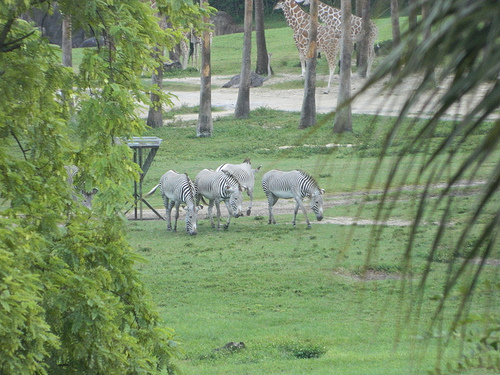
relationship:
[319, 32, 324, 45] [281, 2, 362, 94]
spot on giraffe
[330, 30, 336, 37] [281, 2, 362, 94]
spot on giraffe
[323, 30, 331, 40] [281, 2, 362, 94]
spot on giraffe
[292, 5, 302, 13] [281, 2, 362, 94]
spot on giraffe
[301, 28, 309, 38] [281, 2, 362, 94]
spot on giraffe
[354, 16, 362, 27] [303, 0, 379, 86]
spot on giraffe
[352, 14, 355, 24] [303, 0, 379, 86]
spot on giraffe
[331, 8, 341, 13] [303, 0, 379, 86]
spot on giraffe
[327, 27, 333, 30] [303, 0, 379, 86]
spot on giraffe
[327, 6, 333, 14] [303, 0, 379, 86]
spot on giraffe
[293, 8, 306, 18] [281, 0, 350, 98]
spot on giraffe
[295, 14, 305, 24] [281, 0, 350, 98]
spot on giraffe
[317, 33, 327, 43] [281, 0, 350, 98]
spot on giraffe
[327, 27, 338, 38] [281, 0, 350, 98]
spot on giraffe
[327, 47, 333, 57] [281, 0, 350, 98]
spot on giraffe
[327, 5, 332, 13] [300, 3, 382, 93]
spot on giraffe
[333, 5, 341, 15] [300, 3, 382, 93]
spot on giraffe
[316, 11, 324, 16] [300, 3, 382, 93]
spot on giraffe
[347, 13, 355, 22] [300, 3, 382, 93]
spot on giraffe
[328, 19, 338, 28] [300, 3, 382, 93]
spot on giraffe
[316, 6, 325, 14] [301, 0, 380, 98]
spot on giraffe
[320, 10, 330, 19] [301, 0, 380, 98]
spot on giraffe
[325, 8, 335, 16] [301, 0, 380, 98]
spot on giraffe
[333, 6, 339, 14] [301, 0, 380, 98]
spot on giraffe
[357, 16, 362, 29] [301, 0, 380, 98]
spot on giraffe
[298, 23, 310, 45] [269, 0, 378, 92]
spot on giraffe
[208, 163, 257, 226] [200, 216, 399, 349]
zebra eating grass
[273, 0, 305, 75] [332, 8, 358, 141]
giraffe behind tree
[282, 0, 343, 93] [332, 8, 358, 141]
giraffe behind tree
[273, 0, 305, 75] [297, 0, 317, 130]
giraffe behind tree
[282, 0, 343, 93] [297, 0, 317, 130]
giraffe behind tree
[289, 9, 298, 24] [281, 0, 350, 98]
spot on giraffe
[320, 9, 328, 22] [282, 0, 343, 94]
spot on giraffe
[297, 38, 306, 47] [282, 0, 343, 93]
spot on giraffe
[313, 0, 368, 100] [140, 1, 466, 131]
giraffe in background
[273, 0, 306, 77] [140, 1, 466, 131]
giraffe in background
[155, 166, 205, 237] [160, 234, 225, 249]
zebra eating grass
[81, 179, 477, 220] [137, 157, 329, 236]
path behind zebras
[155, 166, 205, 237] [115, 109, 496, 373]
zebra eating grass